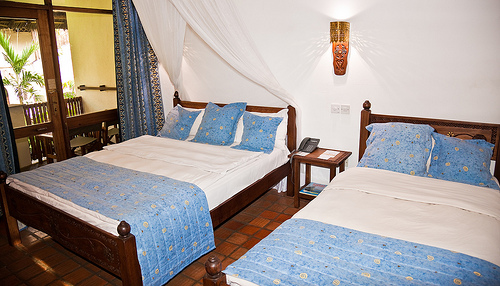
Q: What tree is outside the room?
A: Palm.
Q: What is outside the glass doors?
A: Balcony.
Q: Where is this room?
A: Hotel.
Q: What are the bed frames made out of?
A: Dark wood.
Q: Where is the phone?
A: On table between beds.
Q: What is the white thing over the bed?
A: Mosquito net.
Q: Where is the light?
A: On the wall.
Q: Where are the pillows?
A: On the bed.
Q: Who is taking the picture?
A: A photographer.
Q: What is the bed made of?
A: Wood.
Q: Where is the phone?
A: On the night table.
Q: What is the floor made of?
A: Tiles.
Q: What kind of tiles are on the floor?
A: Reddish brown tiles.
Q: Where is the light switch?
A: Under the light.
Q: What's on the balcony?
A: Chairs.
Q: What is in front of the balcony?
A: A palm tree.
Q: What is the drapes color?
A: Blue.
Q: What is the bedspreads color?
A: Blue.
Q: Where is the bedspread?
A: At the foot of the bed.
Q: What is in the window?
A: Tree.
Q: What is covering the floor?
A: Tiles.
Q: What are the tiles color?
A: Brown.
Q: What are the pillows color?
A: Blue.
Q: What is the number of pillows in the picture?
A: 5.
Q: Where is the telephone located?
A: On table.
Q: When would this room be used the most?
A: At Night.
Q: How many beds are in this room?
A: Two.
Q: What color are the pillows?
A: Blue.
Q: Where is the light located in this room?
A: On Wall.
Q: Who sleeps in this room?
A: Guests.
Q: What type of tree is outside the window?
A: Palm Tree.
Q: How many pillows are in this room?
A: Five.